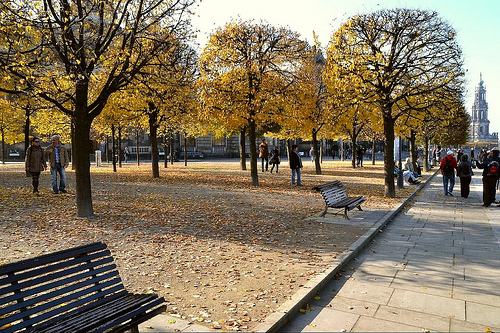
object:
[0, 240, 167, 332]
bench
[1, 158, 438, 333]
leaf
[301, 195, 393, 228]
base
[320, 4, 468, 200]
leaf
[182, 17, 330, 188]
leaf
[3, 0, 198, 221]
tree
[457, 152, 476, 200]
person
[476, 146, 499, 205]
person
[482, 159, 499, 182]
backpack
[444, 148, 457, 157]
hat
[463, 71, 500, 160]
building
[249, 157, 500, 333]
street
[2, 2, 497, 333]
park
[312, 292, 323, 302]
leaf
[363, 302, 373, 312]
leaf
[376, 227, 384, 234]
leaf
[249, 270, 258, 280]
leaf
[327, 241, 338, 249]
leaf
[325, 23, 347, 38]
leaf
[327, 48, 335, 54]
leaf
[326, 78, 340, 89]
leaf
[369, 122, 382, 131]
leaf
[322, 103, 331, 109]
leaf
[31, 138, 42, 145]
sunglasses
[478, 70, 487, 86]
top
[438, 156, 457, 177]
backpack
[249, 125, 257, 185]
trunk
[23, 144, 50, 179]
jacket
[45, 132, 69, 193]
man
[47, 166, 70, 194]
pants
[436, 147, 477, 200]
group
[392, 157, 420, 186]
person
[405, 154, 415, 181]
person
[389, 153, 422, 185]
group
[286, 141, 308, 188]
person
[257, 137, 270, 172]
person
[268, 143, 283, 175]
person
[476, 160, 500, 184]
jacket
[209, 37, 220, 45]
leaf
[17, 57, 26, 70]
leaf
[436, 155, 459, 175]
shirt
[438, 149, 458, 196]
man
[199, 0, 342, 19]
sky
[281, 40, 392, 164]
building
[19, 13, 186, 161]
building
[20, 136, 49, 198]
wife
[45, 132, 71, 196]
husband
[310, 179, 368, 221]
bench